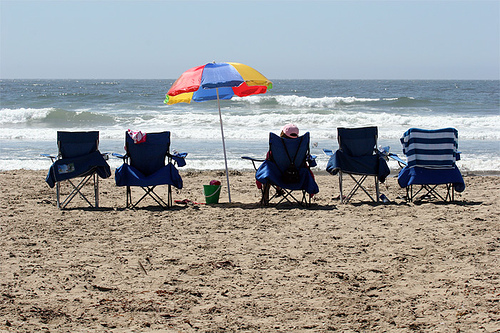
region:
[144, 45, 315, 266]
a tall beach umbrella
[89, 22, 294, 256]
blue red yellow umbrella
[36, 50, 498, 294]
beach chairs on the sand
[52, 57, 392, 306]
a beach with sand and water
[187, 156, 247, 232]
a sand pail under the umbrella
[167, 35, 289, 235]
an umbrella standing in the sand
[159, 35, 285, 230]
an umbrella leaning to the side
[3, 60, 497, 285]
five chairs on the sand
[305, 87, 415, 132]
a body of water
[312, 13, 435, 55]
a clear blue sky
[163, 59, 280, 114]
red, blue and yellow beach umbrella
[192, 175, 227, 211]
green sand pail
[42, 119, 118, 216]
folding blue camp or beach chair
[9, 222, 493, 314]
a sandy beach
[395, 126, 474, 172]
blue and white striped beach towel over back of beach chair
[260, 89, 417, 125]
waves rolling in towards the beach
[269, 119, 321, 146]
back of person's head, wearing an pink cap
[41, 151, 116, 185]
sack on back of beach chair for carrying chair when it is folded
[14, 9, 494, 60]
a clear blue sky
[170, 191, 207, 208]
red flip flops in the sand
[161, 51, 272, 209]
Red, blue and yellow umbrella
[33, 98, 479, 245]
Five beach chairs lined up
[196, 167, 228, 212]
A green bucket with a white handle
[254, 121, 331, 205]
Person sitting in chair with pink hat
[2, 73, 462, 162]
Waves coming in to shore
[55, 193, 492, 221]
Shadows cast by chairs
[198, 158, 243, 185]
Little mound of sand in front of umbrella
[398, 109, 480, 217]
Blue and white towel on back of chair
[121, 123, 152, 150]
Little red and white cloth on chair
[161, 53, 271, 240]
Umbrella stuck in the sand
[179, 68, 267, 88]
this is a umbrella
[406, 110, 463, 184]
this is a chair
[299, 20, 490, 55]
this is the sky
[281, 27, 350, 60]
thew sky is blue in color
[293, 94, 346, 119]
these are the waves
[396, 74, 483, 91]
this is water body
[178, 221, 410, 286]
this is the beach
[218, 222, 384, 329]
the beach is sandy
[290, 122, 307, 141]
this is a cap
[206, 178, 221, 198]
this is a container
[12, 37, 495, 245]
row of five chairs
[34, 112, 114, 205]
blue travel chair in sand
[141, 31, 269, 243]
colorful umbrella used for shade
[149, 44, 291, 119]
red blue and yellow umbrella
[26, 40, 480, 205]
small waves in the ocean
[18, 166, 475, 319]
sand full of foot tracks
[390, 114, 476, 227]
chair with blue and white towel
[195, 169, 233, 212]
small green bucket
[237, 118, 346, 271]
chair with person sitting in it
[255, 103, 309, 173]
person wearing a hat